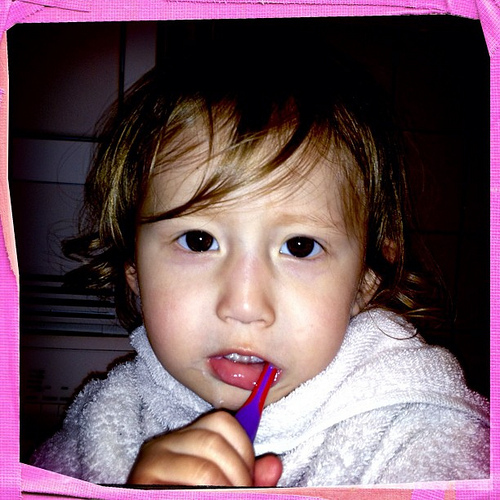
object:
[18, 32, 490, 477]
toddler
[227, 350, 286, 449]
toothbrush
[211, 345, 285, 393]
mouth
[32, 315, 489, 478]
shirt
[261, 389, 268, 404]
red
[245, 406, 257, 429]
purple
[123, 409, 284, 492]
hand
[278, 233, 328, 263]
eyes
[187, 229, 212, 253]
brown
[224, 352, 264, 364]
teeth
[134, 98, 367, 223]
bangs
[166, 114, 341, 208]
forehead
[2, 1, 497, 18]
border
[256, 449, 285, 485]
thumb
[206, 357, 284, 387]
lip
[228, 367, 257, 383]
wet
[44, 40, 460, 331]
hair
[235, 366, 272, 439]
blue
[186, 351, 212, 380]
toothpaste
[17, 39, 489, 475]
indoor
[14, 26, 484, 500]
scene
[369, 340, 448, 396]
fluffy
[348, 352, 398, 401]
white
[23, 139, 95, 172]
white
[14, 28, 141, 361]
walls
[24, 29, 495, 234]
background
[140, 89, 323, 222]
long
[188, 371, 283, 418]
chin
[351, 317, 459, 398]
hood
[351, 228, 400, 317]
ear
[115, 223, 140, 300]
ear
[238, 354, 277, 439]
handle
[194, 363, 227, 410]
drool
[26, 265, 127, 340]
vent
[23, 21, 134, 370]
building